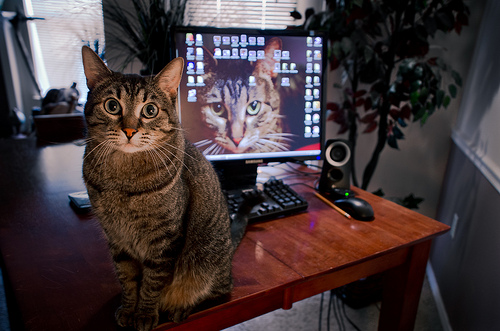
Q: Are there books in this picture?
A: No, there are no books.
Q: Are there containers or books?
A: No, there are no books or containers.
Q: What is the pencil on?
A: The pencil is on the table.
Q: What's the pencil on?
A: The pencil is on the table.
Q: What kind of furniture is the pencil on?
A: The pencil is on the table.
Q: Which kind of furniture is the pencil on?
A: The pencil is on the table.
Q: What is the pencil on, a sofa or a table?
A: The pencil is on a table.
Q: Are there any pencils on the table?
A: Yes, there is a pencil on the table.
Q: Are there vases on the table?
A: No, there is a pencil on the table.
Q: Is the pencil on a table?
A: Yes, the pencil is on a table.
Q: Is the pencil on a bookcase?
A: No, the pencil is on a table.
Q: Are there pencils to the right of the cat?
A: Yes, there is a pencil to the right of the cat.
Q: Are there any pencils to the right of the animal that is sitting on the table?
A: Yes, there is a pencil to the right of the cat.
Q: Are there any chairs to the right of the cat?
A: No, there is a pencil to the right of the cat.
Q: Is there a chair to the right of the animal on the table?
A: No, there is a pencil to the right of the cat.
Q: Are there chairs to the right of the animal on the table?
A: No, there is a pencil to the right of the cat.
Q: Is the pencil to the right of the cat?
A: Yes, the pencil is to the right of the cat.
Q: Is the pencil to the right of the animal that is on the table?
A: Yes, the pencil is to the right of the cat.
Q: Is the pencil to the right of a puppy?
A: No, the pencil is to the right of the cat.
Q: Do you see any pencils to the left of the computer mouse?
A: Yes, there is a pencil to the left of the computer mouse.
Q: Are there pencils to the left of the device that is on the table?
A: Yes, there is a pencil to the left of the computer mouse.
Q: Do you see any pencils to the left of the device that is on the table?
A: Yes, there is a pencil to the left of the computer mouse.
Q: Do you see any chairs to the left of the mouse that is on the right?
A: No, there is a pencil to the left of the computer mouse.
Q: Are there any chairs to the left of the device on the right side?
A: No, there is a pencil to the left of the computer mouse.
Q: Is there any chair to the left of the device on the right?
A: No, there is a pencil to the left of the computer mouse.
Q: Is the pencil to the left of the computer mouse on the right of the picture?
A: Yes, the pencil is to the left of the computer mouse.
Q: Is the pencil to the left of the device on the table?
A: Yes, the pencil is to the left of the computer mouse.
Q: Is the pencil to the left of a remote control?
A: No, the pencil is to the left of the computer mouse.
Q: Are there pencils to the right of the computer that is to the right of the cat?
A: Yes, there is a pencil to the right of the computer.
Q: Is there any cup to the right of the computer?
A: No, there is a pencil to the right of the computer.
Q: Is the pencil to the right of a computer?
A: Yes, the pencil is to the right of a computer.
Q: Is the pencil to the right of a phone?
A: No, the pencil is to the right of a computer.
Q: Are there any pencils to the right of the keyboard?
A: Yes, there is a pencil to the right of the keyboard.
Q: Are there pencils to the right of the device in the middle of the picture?
A: Yes, there is a pencil to the right of the keyboard.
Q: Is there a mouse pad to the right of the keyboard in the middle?
A: No, there is a pencil to the right of the keyboard.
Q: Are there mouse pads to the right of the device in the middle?
A: No, there is a pencil to the right of the keyboard.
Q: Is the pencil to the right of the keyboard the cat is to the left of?
A: Yes, the pencil is to the right of the keyboard.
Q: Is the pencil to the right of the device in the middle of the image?
A: Yes, the pencil is to the right of the keyboard.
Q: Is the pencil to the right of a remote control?
A: No, the pencil is to the right of the keyboard.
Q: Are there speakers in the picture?
A: Yes, there is a speaker.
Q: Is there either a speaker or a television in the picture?
A: Yes, there is a speaker.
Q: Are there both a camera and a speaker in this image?
A: No, there is a speaker but no cameras.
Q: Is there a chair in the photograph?
A: No, there are no chairs.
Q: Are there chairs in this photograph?
A: No, there are no chairs.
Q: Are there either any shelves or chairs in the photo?
A: No, there are no chairs or shelves.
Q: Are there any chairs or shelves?
A: No, there are no chairs or shelves.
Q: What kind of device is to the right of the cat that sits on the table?
A: The device is a speaker.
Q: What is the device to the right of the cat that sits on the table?
A: The device is a speaker.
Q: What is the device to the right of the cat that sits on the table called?
A: The device is a speaker.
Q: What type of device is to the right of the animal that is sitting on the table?
A: The device is a speaker.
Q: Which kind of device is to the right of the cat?
A: The device is a speaker.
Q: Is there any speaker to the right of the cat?
A: Yes, there is a speaker to the right of the cat.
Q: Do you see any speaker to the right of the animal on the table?
A: Yes, there is a speaker to the right of the cat.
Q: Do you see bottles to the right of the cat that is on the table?
A: No, there is a speaker to the right of the cat.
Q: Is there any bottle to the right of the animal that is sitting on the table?
A: No, there is a speaker to the right of the cat.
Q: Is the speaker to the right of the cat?
A: Yes, the speaker is to the right of the cat.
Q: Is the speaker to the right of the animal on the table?
A: Yes, the speaker is to the right of the cat.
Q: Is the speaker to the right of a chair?
A: No, the speaker is to the right of the cat.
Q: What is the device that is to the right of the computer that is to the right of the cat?
A: The device is a speaker.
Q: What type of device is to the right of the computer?
A: The device is a speaker.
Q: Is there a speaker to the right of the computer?
A: Yes, there is a speaker to the right of the computer.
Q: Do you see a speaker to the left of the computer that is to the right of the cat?
A: No, the speaker is to the right of the computer.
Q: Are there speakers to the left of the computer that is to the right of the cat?
A: No, the speaker is to the right of the computer.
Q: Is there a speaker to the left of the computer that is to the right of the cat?
A: No, the speaker is to the right of the computer.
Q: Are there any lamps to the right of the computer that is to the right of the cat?
A: No, there is a speaker to the right of the computer.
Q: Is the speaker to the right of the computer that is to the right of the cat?
A: Yes, the speaker is to the right of the computer.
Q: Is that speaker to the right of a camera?
A: No, the speaker is to the right of the computer.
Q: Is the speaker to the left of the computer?
A: No, the speaker is to the right of the computer.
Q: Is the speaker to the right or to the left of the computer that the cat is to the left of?
A: The speaker is to the right of the computer.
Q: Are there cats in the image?
A: Yes, there is a cat.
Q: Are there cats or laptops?
A: Yes, there is a cat.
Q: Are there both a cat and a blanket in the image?
A: No, there is a cat but no blankets.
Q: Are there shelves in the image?
A: No, there are no shelves.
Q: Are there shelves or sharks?
A: No, there are no shelves or sharks.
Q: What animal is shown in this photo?
A: The animal is a cat.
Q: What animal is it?
A: The animal is a cat.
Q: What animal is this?
A: This is a cat.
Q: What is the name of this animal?
A: This is a cat.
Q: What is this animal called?
A: This is a cat.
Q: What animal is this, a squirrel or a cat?
A: This is a cat.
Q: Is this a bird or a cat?
A: This is a cat.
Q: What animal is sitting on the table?
A: The cat is sitting on the table.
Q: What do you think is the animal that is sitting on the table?
A: The animal is a cat.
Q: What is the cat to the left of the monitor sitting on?
A: The cat is sitting on the table.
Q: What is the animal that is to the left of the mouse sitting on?
A: The cat is sitting on the table.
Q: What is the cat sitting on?
A: The cat is sitting on the table.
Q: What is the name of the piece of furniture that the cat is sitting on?
A: The piece of furniture is a table.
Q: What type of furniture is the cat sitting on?
A: The cat is sitting on the table.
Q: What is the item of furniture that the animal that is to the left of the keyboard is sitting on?
A: The piece of furniture is a table.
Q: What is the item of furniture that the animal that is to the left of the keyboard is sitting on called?
A: The piece of furniture is a table.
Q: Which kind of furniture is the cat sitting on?
A: The cat is sitting on the table.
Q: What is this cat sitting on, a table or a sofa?
A: The cat is sitting on a table.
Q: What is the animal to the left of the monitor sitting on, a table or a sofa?
A: The cat is sitting on a table.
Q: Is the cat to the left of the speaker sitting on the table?
A: Yes, the cat is sitting on the table.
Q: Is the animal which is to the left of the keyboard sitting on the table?
A: Yes, the cat is sitting on the table.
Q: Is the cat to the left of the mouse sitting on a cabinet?
A: No, the cat is sitting on the table.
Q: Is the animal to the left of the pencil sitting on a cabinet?
A: No, the cat is sitting on the table.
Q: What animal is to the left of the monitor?
A: The animal is a cat.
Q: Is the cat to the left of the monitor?
A: Yes, the cat is to the left of the monitor.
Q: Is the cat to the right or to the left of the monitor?
A: The cat is to the left of the monitor.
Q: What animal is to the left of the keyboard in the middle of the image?
A: The animal is a cat.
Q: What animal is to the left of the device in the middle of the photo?
A: The animal is a cat.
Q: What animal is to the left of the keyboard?
A: The animal is a cat.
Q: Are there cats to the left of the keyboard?
A: Yes, there is a cat to the left of the keyboard.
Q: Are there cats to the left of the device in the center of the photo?
A: Yes, there is a cat to the left of the keyboard.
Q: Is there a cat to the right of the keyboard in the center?
A: No, the cat is to the left of the keyboard.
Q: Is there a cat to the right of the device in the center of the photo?
A: No, the cat is to the left of the keyboard.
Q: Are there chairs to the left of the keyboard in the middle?
A: No, there is a cat to the left of the keyboard.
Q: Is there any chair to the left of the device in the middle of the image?
A: No, there is a cat to the left of the keyboard.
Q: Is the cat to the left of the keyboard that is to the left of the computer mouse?
A: Yes, the cat is to the left of the keyboard.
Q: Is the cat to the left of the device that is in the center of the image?
A: Yes, the cat is to the left of the keyboard.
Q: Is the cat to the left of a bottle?
A: No, the cat is to the left of the keyboard.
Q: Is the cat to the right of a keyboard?
A: No, the cat is to the left of a keyboard.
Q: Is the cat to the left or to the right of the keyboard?
A: The cat is to the left of the keyboard.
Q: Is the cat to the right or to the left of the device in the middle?
A: The cat is to the left of the keyboard.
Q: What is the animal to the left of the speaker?
A: The animal is a cat.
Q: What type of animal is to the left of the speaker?
A: The animal is a cat.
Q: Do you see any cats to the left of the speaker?
A: Yes, there is a cat to the left of the speaker.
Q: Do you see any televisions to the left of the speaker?
A: No, there is a cat to the left of the speaker.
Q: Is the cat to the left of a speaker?
A: Yes, the cat is to the left of a speaker.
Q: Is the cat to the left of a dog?
A: No, the cat is to the left of a speaker.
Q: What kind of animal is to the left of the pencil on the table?
A: The animal is a cat.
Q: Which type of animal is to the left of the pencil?
A: The animal is a cat.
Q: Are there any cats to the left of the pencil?
A: Yes, there is a cat to the left of the pencil.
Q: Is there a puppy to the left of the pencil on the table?
A: No, there is a cat to the left of the pencil.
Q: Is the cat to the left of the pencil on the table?
A: Yes, the cat is to the left of the pencil.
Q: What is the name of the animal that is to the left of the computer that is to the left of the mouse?
A: The animal is a cat.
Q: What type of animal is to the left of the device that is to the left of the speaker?
A: The animal is a cat.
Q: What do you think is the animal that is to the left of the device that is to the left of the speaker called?
A: The animal is a cat.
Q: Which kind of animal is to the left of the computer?
A: The animal is a cat.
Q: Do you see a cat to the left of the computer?
A: Yes, there is a cat to the left of the computer.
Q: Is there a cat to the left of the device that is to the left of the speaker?
A: Yes, there is a cat to the left of the computer.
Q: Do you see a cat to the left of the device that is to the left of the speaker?
A: Yes, there is a cat to the left of the computer.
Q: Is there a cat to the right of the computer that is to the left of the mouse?
A: No, the cat is to the left of the computer.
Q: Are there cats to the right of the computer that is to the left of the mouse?
A: No, the cat is to the left of the computer.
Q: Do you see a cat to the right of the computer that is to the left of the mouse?
A: No, the cat is to the left of the computer.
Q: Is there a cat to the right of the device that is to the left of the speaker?
A: No, the cat is to the left of the computer.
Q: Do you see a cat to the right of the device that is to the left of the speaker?
A: No, the cat is to the left of the computer.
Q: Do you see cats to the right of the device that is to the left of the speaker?
A: No, the cat is to the left of the computer.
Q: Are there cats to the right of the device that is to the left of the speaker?
A: No, the cat is to the left of the computer.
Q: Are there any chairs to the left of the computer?
A: No, there is a cat to the left of the computer.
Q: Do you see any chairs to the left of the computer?
A: No, there is a cat to the left of the computer.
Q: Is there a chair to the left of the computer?
A: No, there is a cat to the left of the computer.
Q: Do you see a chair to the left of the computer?
A: No, there is a cat to the left of the computer.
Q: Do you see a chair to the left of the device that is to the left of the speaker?
A: No, there is a cat to the left of the computer.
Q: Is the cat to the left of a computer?
A: Yes, the cat is to the left of a computer.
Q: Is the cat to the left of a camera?
A: No, the cat is to the left of a computer.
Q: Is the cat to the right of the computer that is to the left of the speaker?
A: No, the cat is to the left of the computer.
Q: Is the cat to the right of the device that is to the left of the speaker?
A: No, the cat is to the left of the computer.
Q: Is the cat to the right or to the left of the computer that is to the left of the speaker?
A: The cat is to the left of the computer.